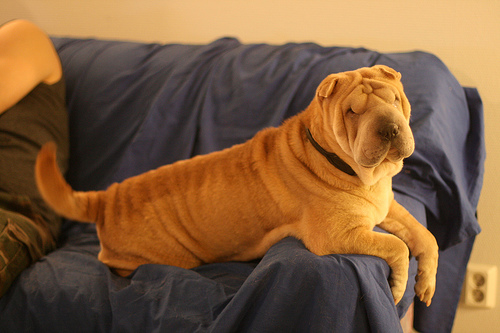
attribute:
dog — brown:
[51, 63, 467, 305]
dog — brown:
[33, 62, 440, 307]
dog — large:
[40, 36, 468, 313]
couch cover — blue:
[158, 262, 368, 331]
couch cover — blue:
[2, 35, 485, 330]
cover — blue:
[3, 51, 493, 321]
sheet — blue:
[0, 36, 478, 331]